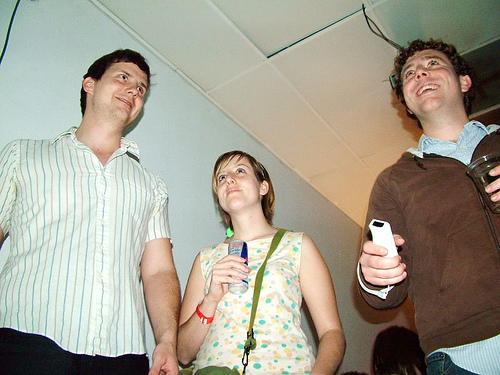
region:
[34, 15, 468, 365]
three people in room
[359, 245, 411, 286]
a hand holding a controller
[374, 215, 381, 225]
a black square on the controller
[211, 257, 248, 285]
a hand holding a can of soda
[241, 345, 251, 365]
a black clip on a bag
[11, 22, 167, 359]
a man wearing a white stripe shirt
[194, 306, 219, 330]
a red band on a wrist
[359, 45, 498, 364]
a man wearing a brown shirt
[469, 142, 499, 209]
a clear cup in a hand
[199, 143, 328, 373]
a woman wearing a floral blouse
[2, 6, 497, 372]
three young people are having fun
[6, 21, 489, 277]
three young people are smiling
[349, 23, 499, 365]
man wears a brown jacket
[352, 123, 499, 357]
brown jacket has a hood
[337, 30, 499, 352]
man holds a game control on right hand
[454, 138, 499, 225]
a cup of drink in a hand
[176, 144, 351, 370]
woman is looking up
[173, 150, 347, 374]
woman has a green strap over left shoulder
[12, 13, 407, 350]
wall and ceiling of room are white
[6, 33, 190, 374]
man wears a white striped shirt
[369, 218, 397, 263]
the wiimote is white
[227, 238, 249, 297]
a can of redbull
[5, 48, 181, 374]
the man is smiling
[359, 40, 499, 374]
the smiling man with a wiimote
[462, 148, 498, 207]
a clear cup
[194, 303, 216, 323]
a lady's wrist band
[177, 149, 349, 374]
the lady is holding a can of soda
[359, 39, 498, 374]
the man has a brown jacket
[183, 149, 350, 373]
this woman has a spotted shirt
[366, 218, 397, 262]
this object is white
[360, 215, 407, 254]
part of a white game controller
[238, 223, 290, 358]
a long green strap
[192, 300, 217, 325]
a red bracelet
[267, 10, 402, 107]
a piece of white ceiling tile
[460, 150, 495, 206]
part of a plastic cup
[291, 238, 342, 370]
the arm of a woman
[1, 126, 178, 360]
a man's short sleeve shirt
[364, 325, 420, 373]
the head of a woman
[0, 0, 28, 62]
part of a black cord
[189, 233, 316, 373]
a woman's flower tank top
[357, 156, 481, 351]
the jacket is brown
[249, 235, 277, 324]
bag's strap is green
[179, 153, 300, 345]
woman holding a can of drink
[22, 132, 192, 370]
the shirt is stripes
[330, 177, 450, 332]
man holding a console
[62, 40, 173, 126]
the hair is dark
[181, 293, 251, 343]
the bracelet is red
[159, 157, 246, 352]
woman wearing a bracelet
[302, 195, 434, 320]
the console is white